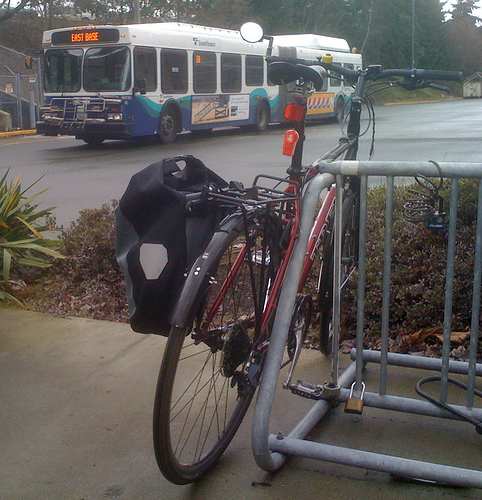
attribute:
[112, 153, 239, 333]
backpack — black and gray, vinyl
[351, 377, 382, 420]
paddle lock — brass and silver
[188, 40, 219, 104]
windows — large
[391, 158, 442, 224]
lock — blue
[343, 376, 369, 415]
padlock — gold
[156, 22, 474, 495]
bike — Black and red 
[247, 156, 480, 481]
bike rack — grey, gray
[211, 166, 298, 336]
wheel rack — black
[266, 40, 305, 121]
extender — black, flexible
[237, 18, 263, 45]
bicycle mirror — black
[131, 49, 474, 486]
bike — red and black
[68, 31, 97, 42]
sign — orange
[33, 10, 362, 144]
bus — large , long, blue and white